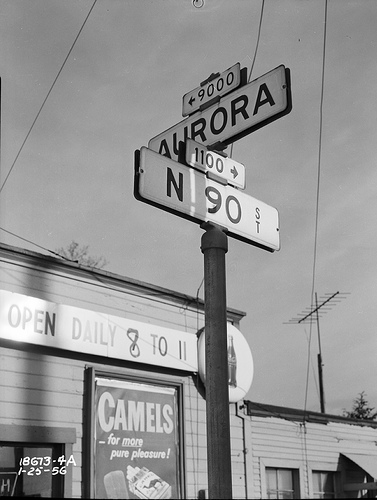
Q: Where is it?
A: This is at the store.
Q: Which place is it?
A: It is a store.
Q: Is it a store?
A: Yes, it is a store.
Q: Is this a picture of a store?
A: Yes, it is showing a store.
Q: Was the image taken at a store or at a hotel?
A: It was taken at a store.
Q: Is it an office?
A: No, it is a store.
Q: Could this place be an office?
A: No, it is a store.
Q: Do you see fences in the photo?
A: No, there are no fences.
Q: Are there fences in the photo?
A: No, there are no fences.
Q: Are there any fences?
A: No, there are no fences.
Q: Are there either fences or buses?
A: No, there are no fences or buses.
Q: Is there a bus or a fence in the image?
A: No, there are no fences or buses.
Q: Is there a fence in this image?
A: No, there are no fences.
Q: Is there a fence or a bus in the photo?
A: No, there are no fences or buses.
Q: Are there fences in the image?
A: No, there are no fences.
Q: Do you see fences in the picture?
A: No, there are no fences.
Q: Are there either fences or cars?
A: No, there are no fences or cars.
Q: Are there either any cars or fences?
A: No, there are no fences or cars.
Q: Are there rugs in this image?
A: No, there are no rugs.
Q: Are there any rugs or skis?
A: No, there are no rugs or skis.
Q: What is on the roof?
A: The antenna is on the roof.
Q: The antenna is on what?
A: The antenna is on the roof.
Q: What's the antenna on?
A: The antenna is on the roof.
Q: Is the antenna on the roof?
A: Yes, the antenna is on the roof.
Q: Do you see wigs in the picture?
A: No, there are no wigs.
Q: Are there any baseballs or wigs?
A: No, there are no wigs or baseballs.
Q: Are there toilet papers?
A: No, there are no toilet papers.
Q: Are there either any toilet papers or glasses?
A: No, there are no toilet papers or glasses.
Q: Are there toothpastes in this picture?
A: No, there are no toothpastes.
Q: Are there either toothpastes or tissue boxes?
A: No, there are no toothpastes or tissue boxes.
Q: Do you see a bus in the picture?
A: No, there are no buses.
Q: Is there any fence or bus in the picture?
A: No, there are no buses or fences.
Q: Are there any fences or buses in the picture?
A: No, there are no buses or fences.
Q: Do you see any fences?
A: No, there are no fences.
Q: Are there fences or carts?
A: No, there are no fences or carts.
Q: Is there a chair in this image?
A: No, there are no chairs.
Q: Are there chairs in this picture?
A: No, there are no chairs.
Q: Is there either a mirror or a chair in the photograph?
A: No, there are no chairs or mirrors.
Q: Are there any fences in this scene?
A: No, there are no fences.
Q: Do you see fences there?
A: No, there are no fences.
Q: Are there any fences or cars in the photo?
A: No, there are no fences or cars.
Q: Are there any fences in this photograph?
A: No, there are no fences.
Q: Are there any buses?
A: No, there are no buses.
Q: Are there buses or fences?
A: No, there are no buses or fences.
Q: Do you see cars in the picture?
A: No, there are no cars.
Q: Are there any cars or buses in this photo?
A: No, there are no cars or buses.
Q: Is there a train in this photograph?
A: No, there are no trains.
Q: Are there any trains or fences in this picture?
A: No, there are no trains or fences.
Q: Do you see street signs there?
A: Yes, there is a street sign.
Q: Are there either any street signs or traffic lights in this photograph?
A: Yes, there is a street sign.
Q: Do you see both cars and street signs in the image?
A: No, there is a street sign but no cars.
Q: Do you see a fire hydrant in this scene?
A: No, there are no fire hydrants.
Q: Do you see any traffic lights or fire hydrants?
A: No, there are no fire hydrants or traffic lights.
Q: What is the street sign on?
A: The street sign is on the pole.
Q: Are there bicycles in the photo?
A: No, there are no bicycles.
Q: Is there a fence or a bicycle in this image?
A: No, there are no bicycles or fences.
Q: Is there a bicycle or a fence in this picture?
A: No, there are no bicycles or fences.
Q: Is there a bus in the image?
A: No, there are no buses.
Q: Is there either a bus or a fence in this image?
A: No, there are no buses or fences.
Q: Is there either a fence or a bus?
A: No, there are no buses or fences.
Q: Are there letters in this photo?
A: Yes, there are letters.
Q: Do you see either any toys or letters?
A: Yes, there are letters.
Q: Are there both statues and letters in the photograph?
A: No, there are letters but no statues.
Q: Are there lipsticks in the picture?
A: No, there are no lipsticks.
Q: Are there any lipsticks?
A: No, there are no lipsticks.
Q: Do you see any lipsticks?
A: No, there are no lipsticks.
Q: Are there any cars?
A: No, there are no cars.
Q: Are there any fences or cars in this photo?
A: No, there are no cars or fences.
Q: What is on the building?
A: The sign is on the building.